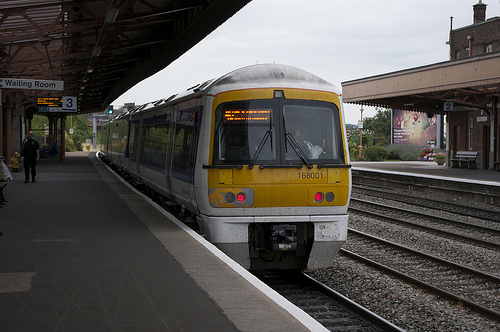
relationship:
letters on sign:
[2, 78, 59, 88] [7, 64, 65, 96]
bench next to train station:
[451, 148, 478, 166] [339, 46, 499, 181]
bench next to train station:
[1, 175, 11, 202] [0, 3, 61, 203]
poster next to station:
[386, 105, 441, 149] [342, 50, 484, 182]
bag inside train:
[304, 138, 332, 168] [90, 58, 352, 270]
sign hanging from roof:
[59, 99, 79, 111] [3, 1, 253, 112]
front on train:
[209, 78, 350, 273] [90, 58, 352, 270]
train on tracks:
[90, 58, 352, 270] [254, 272, 406, 330]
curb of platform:
[87, 143, 334, 330] [0, 150, 330, 330]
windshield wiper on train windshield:
[251, 129, 274, 167] [217, 93, 347, 169]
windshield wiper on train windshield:
[285, 129, 313, 169] [217, 93, 347, 169]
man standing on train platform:
[18, 127, 42, 188] [1, 150, 332, 330]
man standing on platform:
[18, 127, 42, 188] [6, 132, 339, 322]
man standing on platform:
[18, 127, 42, 188] [0, 150, 330, 330]